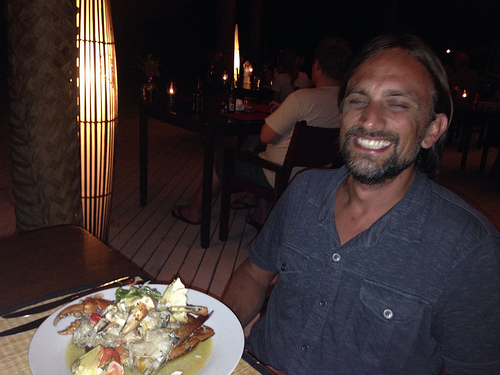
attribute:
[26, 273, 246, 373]
plate — white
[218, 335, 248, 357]
plate — WHITE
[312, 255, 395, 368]
shirt — BLUE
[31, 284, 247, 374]
plate — round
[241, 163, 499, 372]
shirt — blue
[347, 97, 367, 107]
eye — closed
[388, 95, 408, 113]
eye — closed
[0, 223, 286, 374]
table — wooden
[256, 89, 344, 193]
t shirt — white